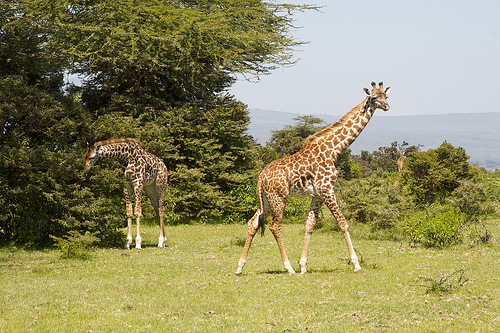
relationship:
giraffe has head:
[215, 74, 399, 291] [359, 77, 394, 120]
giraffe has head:
[72, 127, 180, 256] [76, 134, 107, 180]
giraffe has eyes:
[215, 74, 399, 291] [371, 95, 392, 102]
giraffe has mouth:
[215, 74, 399, 291] [379, 105, 395, 112]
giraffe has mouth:
[72, 127, 180, 256] [83, 168, 92, 174]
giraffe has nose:
[215, 74, 399, 291] [380, 102, 393, 111]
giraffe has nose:
[72, 127, 180, 256] [80, 166, 88, 174]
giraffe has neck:
[215, 74, 399, 291] [328, 94, 367, 157]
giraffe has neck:
[72, 127, 180, 256] [104, 134, 132, 168]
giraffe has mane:
[215, 74, 399, 291] [286, 93, 367, 145]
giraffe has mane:
[72, 127, 180, 256] [89, 135, 140, 148]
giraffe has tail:
[215, 74, 399, 291] [255, 185, 268, 236]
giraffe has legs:
[215, 74, 399, 291] [234, 187, 364, 280]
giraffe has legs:
[72, 127, 180, 256] [114, 182, 171, 252]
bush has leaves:
[0, 0, 500, 261] [29, 7, 259, 90]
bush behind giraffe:
[0, 0, 500, 261] [72, 127, 180, 256]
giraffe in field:
[215, 74, 399, 291] [4, 215, 499, 331]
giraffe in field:
[72, 127, 180, 256] [4, 215, 499, 331]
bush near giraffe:
[71, 107, 250, 235] [72, 127, 180, 256]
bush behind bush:
[0, 0, 500, 261] [0, 0, 500, 261]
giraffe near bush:
[72, 127, 180, 256] [71, 107, 250, 235]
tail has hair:
[255, 185, 268, 236] [257, 213, 271, 235]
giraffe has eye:
[215, 74, 399, 291] [371, 95, 378, 103]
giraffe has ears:
[215, 74, 399, 291] [362, 83, 395, 96]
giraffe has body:
[215, 74, 399, 291] [232, 102, 358, 285]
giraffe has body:
[72, 127, 180, 256] [103, 139, 181, 254]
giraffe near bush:
[72, 127, 180, 256] [0, 0, 500, 261]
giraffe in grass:
[215, 74, 399, 291] [4, 215, 499, 331]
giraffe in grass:
[72, 127, 180, 256] [4, 215, 499, 331]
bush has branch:
[0, 0, 500, 261] [62, 16, 151, 44]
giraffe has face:
[215, 74, 399, 291] [364, 86, 392, 112]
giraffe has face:
[72, 127, 180, 256] [77, 146, 99, 176]